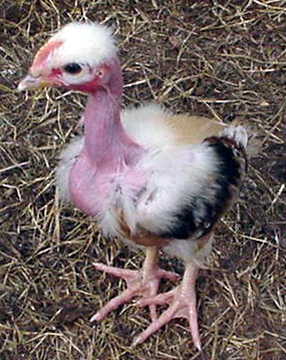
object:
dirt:
[1, 0, 284, 358]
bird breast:
[59, 149, 145, 232]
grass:
[2, 1, 284, 358]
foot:
[125, 279, 205, 350]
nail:
[88, 310, 98, 325]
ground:
[1, 3, 283, 357]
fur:
[65, 121, 104, 180]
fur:
[176, 160, 226, 203]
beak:
[13, 76, 51, 96]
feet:
[90, 257, 158, 329]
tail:
[221, 116, 257, 164]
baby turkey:
[14, 21, 254, 350]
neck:
[79, 89, 134, 158]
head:
[18, 21, 122, 100]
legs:
[88, 232, 200, 346]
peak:
[17, 54, 68, 105]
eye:
[58, 59, 85, 78]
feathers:
[111, 127, 249, 242]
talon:
[96, 244, 211, 342]